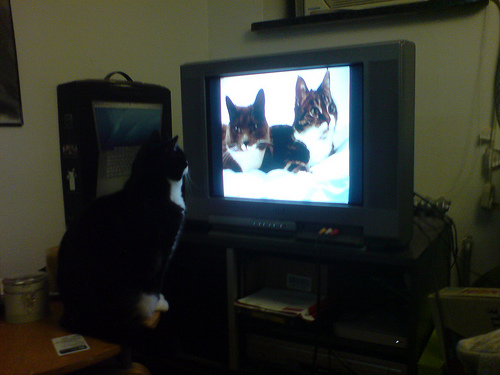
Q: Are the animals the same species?
A: Yes, all the animals are cats.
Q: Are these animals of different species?
A: No, all the animals are cats.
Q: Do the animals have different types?
A: No, all the animals are cats.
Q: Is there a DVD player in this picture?
A: Yes, there is a DVD player.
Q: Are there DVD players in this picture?
A: Yes, there is a DVD player.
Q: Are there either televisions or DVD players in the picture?
A: Yes, there is a DVD player.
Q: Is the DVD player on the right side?
A: Yes, the DVD player is on the right of the image.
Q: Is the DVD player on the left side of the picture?
A: No, the DVD player is on the right of the image.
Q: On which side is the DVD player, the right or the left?
A: The DVD player is on the right of the image.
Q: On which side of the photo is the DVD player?
A: The DVD player is on the right of the image.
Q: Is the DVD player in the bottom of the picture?
A: Yes, the DVD player is in the bottom of the image.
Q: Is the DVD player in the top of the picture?
A: No, the DVD player is in the bottom of the image.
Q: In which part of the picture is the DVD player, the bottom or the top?
A: The DVD player is in the bottom of the image.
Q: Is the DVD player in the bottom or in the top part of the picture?
A: The DVD player is in the bottom of the image.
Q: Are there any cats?
A: Yes, there are cats.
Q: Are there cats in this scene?
A: Yes, there are cats.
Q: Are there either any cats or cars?
A: Yes, there are cats.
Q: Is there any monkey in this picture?
A: No, there are no monkeys.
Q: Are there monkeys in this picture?
A: No, there are no monkeys.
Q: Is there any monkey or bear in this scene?
A: No, there are no monkeys or bears.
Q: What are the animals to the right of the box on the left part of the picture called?
A: The animals are cats.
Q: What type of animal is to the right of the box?
A: The animals are cats.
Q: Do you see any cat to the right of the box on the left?
A: Yes, there are cats to the right of the box.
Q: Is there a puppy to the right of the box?
A: No, there are cats to the right of the box.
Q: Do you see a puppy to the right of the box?
A: No, there are cats to the right of the box.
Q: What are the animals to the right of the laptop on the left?
A: The animals are cats.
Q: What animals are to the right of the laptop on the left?
A: The animals are cats.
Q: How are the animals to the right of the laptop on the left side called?
A: The animals are cats.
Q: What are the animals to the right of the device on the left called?
A: The animals are cats.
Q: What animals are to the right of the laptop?
A: The animals are cats.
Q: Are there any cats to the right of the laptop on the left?
A: Yes, there are cats to the right of the laptop.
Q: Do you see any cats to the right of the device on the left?
A: Yes, there are cats to the right of the laptop.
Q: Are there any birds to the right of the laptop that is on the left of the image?
A: No, there are cats to the right of the laptop.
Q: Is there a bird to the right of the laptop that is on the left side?
A: No, there are cats to the right of the laptop.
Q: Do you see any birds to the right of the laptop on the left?
A: No, there are cats to the right of the laptop.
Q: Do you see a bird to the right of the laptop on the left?
A: No, there are cats to the right of the laptop.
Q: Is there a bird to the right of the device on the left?
A: No, there are cats to the right of the laptop.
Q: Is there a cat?
A: Yes, there is a cat.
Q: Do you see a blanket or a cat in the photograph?
A: Yes, there is a cat.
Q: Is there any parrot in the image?
A: No, there are no parrots.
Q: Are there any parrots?
A: No, there are no parrots.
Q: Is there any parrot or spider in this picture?
A: No, there are no parrots or spiders.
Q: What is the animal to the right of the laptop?
A: The animal is a cat.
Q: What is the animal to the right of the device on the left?
A: The animal is a cat.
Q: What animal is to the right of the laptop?
A: The animal is a cat.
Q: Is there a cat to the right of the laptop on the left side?
A: Yes, there is a cat to the right of the laptop.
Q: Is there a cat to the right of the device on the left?
A: Yes, there is a cat to the right of the laptop.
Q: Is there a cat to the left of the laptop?
A: No, the cat is to the right of the laptop.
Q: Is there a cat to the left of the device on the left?
A: No, the cat is to the right of the laptop.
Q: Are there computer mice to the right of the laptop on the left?
A: No, there is a cat to the right of the laptop computer.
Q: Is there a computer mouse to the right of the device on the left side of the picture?
A: No, there is a cat to the right of the laptop computer.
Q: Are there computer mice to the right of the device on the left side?
A: No, there is a cat to the right of the laptop computer.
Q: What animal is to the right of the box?
A: The animal is a cat.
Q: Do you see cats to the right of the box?
A: Yes, there is a cat to the right of the box.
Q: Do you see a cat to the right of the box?
A: Yes, there is a cat to the right of the box.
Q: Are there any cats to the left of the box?
A: No, the cat is to the right of the box.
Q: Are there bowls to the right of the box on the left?
A: No, there is a cat to the right of the box.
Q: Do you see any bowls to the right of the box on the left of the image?
A: No, there is a cat to the right of the box.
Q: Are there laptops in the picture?
A: Yes, there is a laptop.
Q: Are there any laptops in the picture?
A: Yes, there is a laptop.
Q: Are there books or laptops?
A: Yes, there is a laptop.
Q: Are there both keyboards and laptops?
A: No, there is a laptop but no keyboards.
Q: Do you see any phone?
A: No, there are no phones.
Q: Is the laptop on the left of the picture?
A: Yes, the laptop is on the left of the image.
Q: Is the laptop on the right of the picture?
A: No, the laptop is on the left of the image.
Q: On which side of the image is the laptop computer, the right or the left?
A: The laptop computer is on the left of the image.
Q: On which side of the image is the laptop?
A: The laptop is on the left of the image.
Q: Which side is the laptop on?
A: The laptop is on the left of the image.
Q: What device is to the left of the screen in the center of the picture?
A: The device is a laptop.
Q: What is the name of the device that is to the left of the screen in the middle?
A: The device is a laptop.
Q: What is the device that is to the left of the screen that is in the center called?
A: The device is a laptop.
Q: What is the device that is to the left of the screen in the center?
A: The device is a laptop.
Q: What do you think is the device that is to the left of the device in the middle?
A: The device is a laptop.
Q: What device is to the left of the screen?
A: The device is a laptop.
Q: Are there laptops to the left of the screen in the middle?
A: Yes, there is a laptop to the left of the screen.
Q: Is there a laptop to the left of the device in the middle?
A: Yes, there is a laptop to the left of the screen.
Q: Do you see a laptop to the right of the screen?
A: No, the laptop is to the left of the screen.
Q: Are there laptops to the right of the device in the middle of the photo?
A: No, the laptop is to the left of the screen.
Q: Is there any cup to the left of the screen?
A: No, there is a laptop to the left of the screen.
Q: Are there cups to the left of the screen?
A: No, there is a laptop to the left of the screen.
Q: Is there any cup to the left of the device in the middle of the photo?
A: No, there is a laptop to the left of the screen.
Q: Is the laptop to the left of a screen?
A: Yes, the laptop is to the left of a screen.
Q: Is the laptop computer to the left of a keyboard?
A: No, the laptop computer is to the left of a screen.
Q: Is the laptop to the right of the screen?
A: No, the laptop is to the left of the screen.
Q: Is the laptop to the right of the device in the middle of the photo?
A: No, the laptop is to the left of the screen.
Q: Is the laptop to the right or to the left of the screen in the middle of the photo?
A: The laptop is to the left of the screen.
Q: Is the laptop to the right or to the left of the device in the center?
A: The laptop is to the left of the screen.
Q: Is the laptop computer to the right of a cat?
A: No, the laptop computer is to the left of a cat.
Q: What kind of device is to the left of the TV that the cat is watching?
A: The device is a laptop.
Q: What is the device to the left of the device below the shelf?
A: The device is a laptop.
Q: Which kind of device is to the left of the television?
A: The device is a laptop.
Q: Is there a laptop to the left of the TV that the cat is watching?
A: Yes, there is a laptop to the left of the television.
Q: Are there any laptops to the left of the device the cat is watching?
A: Yes, there is a laptop to the left of the television.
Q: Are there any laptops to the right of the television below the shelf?
A: No, the laptop is to the left of the television.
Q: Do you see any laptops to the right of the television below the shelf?
A: No, the laptop is to the left of the television.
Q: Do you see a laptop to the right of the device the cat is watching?
A: No, the laptop is to the left of the television.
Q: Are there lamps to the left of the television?
A: No, there is a laptop to the left of the television.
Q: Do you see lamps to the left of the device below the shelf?
A: No, there is a laptop to the left of the television.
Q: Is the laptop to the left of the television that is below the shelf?
A: Yes, the laptop is to the left of the television.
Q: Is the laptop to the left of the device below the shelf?
A: Yes, the laptop is to the left of the television.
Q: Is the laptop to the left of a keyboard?
A: No, the laptop is to the left of the television.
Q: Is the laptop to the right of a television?
A: No, the laptop is to the left of a television.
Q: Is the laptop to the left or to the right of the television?
A: The laptop is to the left of the television.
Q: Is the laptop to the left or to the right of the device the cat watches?
A: The laptop is to the left of the television.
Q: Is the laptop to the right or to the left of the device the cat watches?
A: The laptop is to the left of the television.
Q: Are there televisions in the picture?
A: Yes, there is a television.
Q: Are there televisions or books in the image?
A: Yes, there is a television.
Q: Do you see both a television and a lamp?
A: No, there is a television but no lamps.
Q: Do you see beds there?
A: No, there are no beds.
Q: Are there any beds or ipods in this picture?
A: No, there are no beds or ipods.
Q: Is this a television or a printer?
A: This is a television.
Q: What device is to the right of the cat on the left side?
A: The device is a television.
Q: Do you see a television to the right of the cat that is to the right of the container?
A: Yes, there is a television to the right of the cat.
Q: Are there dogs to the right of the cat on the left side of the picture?
A: No, there is a television to the right of the cat.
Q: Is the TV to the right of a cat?
A: Yes, the TV is to the right of a cat.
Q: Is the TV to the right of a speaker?
A: No, the TV is to the right of a cat.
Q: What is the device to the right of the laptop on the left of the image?
A: The device is a television.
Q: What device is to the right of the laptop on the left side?
A: The device is a television.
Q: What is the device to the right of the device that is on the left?
A: The device is a television.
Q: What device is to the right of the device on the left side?
A: The device is a television.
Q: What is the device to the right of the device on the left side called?
A: The device is a television.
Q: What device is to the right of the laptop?
A: The device is a television.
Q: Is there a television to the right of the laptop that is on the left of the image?
A: Yes, there is a television to the right of the laptop.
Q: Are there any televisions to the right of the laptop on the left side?
A: Yes, there is a television to the right of the laptop.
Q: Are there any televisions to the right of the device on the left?
A: Yes, there is a television to the right of the laptop.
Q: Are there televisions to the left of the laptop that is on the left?
A: No, the television is to the right of the laptop computer.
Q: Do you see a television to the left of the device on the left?
A: No, the television is to the right of the laptop computer.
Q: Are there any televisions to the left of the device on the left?
A: No, the television is to the right of the laptop computer.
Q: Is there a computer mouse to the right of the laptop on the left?
A: No, there is a television to the right of the laptop.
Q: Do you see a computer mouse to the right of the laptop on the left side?
A: No, there is a television to the right of the laptop.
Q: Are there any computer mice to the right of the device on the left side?
A: No, there is a television to the right of the laptop.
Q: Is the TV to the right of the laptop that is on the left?
A: Yes, the TV is to the right of the laptop.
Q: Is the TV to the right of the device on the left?
A: Yes, the TV is to the right of the laptop.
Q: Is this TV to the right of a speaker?
A: No, the TV is to the right of the laptop.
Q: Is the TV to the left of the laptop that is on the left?
A: No, the TV is to the right of the laptop.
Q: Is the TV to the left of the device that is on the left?
A: No, the TV is to the right of the laptop.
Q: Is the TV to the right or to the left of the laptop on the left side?
A: The TV is to the right of the laptop.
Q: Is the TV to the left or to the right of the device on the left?
A: The TV is to the right of the laptop.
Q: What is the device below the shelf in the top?
A: The device is a television.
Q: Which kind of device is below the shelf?
A: The device is a television.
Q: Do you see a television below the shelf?
A: Yes, there is a television below the shelf.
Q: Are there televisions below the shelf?
A: Yes, there is a television below the shelf.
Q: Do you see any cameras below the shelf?
A: No, there is a television below the shelf.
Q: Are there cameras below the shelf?
A: No, there is a television below the shelf.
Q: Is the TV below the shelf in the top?
A: Yes, the TV is below the shelf.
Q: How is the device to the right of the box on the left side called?
A: The device is a television.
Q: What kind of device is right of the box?
A: The device is a television.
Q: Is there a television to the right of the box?
A: Yes, there is a television to the right of the box.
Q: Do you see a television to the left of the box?
A: No, the television is to the right of the box.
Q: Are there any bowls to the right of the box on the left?
A: No, there is a television to the right of the box.